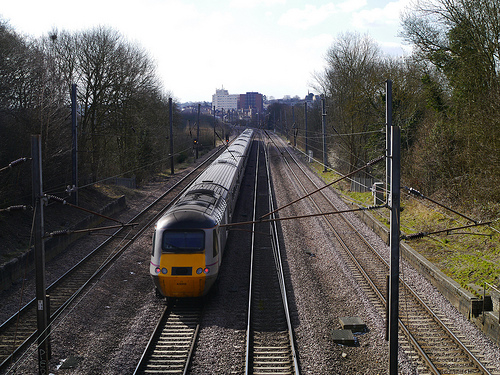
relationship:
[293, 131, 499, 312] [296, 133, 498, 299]
grass on side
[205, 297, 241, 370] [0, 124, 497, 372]
gravel between tracks